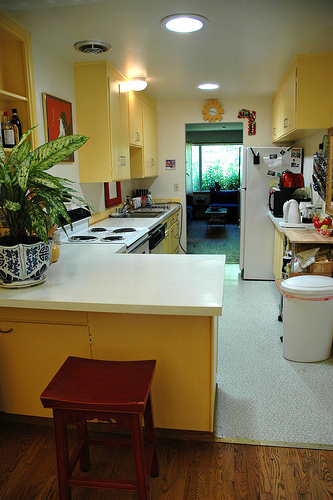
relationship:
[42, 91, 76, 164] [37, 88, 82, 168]
frame on frame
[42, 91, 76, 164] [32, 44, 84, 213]
frame on wall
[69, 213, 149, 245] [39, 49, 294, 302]
stove in kitchen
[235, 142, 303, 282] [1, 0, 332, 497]
refrigerator in kitchen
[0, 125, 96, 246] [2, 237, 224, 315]
plant on counter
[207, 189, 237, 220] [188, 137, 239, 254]
couch in livingroom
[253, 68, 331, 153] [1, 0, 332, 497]
cabinet in kitchen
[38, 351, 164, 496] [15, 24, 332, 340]
chair in kitchen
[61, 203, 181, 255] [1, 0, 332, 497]
stove in kitchen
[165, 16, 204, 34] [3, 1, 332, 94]
ceiling light on ceiling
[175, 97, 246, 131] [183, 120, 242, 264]
clock above doorway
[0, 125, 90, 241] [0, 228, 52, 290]
plant in pot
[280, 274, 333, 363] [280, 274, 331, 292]
garbage can with white lid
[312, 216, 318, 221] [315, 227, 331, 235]
apple in bowl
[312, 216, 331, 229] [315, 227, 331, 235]
apple in bowl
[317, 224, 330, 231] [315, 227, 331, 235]
banana in bowl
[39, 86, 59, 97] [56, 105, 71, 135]
frame in picture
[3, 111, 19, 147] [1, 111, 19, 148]
bottle has bottle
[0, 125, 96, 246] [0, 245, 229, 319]
plant on table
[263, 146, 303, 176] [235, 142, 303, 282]
pictures are on refrigerator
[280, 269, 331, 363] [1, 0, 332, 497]
garbage can in kitchen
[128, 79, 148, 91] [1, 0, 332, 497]
ceiling light in kitchen